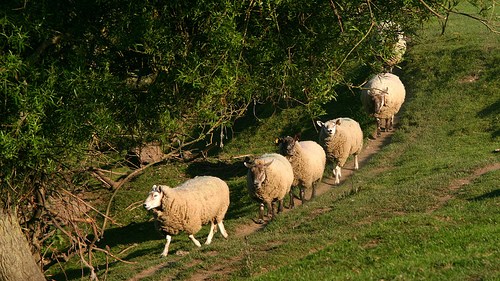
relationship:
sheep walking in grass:
[134, 175, 232, 247] [378, 168, 458, 235]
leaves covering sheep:
[184, 32, 286, 97] [28, 86, 476, 258]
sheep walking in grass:
[134, 175, 232, 247] [6, 4, 497, 279]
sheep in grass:
[137, 173, 232, 247] [84, 7, 498, 279]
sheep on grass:
[134, 175, 232, 247] [84, 7, 498, 279]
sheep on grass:
[246, 153, 307, 220] [84, 7, 498, 279]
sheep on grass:
[275, 135, 325, 206] [84, 7, 498, 279]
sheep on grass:
[315, 116, 360, 178] [84, 7, 498, 279]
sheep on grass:
[358, 70, 405, 135] [84, 7, 498, 279]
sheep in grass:
[143, 119, 395, 211] [348, 184, 473, 259]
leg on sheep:
[153, 231, 185, 266] [121, 156, 271, 275]